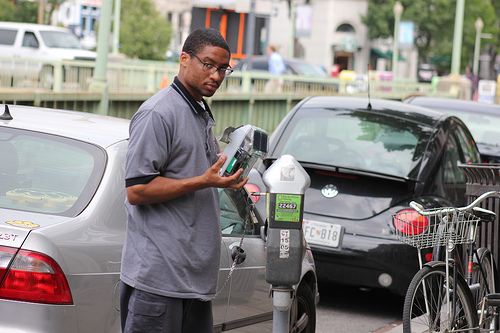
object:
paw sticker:
[4, 219, 39, 231]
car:
[1, 100, 322, 332]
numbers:
[278, 202, 284, 208]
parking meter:
[261, 153, 311, 286]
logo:
[321, 182, 341, 200]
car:
[243, 94, 480, 295]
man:
[118, 26, 250, 332]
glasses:
[193, 51, 233, 77]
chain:
[211, 209, 248, 297]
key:
[247, 188, 266, 197]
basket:
[391, 206, 481, 251]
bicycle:
[389, 188, 499, 333]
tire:
[400, 259, 480, 332]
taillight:
[0, 244, 75, 305]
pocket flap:
[126, 296, 170, 318]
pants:
[118, 277, 215, 333]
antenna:
[0, 102, 14, 121]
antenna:
[364, 63, 371, 110]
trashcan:
[457, 158, 499, 293]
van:
[0, 20, 98, 90]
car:
[400, 92, 500, 164]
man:
[263, 41, 287, 93]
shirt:
[267, 50, 287, 77]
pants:
[263, 77, 285, 93]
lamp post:
[90, 0, 114, 91]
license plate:
[302, 218, 342, 249]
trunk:
[0, 209, 70, 287]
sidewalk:
[383, 300, 461, 332]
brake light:
[394, 209, 427, 235]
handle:
[230, 244, 247, 265]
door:
[218, 180, 265, 332]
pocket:
[125, 297, 166, 332]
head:
[177, 26, 232, 98]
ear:
[178, 50, 191, 69]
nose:
[210, 69, 221, 83]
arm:
[124, 108, 206, 208]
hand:
[203, 154, 250, 190]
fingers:
[217, 167, 245, 185]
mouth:
[203, 80, 219, 91]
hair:
[180, 27, 230, 57]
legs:
[122, 290, 184, 332]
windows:
[270, 108, 434, 178]